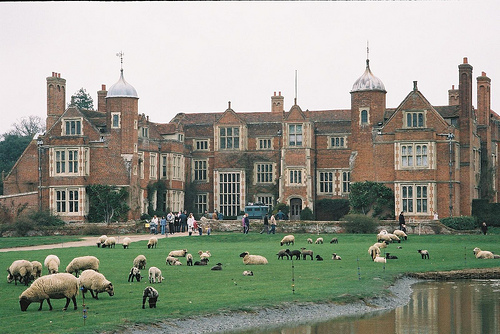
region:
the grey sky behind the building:
[13, 20, 485, 37]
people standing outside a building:
[146, 211, 284, 231]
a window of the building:
[401, 186, 426, 210]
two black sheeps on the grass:
[277, 248, 303, 261]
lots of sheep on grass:
[8, 235, 496, 302]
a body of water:
[231, 268, 491, 331]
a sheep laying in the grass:
[238, 250, 268, 265]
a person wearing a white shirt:
[183, 213, 195, 233]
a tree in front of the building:
[81, 178, 129, 229]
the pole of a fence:
[288, 261, 300, 295]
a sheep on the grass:
[18, 272, 79, 309]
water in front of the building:
[333, 270, 498, 327]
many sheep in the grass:
[7, 218, 496, 314]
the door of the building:
[289, 196, 304, 218]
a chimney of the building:
[46, 73, 62, 120]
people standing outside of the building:
[142, 208, 283, 235]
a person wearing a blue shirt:
[158, 216, 167, 231]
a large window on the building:
[218, 173, 238, 217]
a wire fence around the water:
[38, 241, 496, 321]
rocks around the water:
[191, 302, 405, 332]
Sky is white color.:
[148, 20, 294, 87]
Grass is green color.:
[41, 251, 322, 295]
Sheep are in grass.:
[6, 228, 412, 316]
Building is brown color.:
[36, 110, 448, 212]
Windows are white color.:
[51, 116, 442, 221]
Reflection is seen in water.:
[368, 273, 494, 333]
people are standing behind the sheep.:
[141, 201, 290, 236]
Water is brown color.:
[307, 271, 499, 329]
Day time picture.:
[16, 30, 491, 317]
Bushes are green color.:
[316, 179, 389, 226]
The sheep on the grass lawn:
[6, 228, 496, 310]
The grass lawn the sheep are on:
[2, 229, 499, 331]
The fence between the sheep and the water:
[4, 243, 497, 331]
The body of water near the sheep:
[225, 273, 497, 332]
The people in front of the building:
[144, 207, 495, 239]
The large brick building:
[0, 38, 499, 238]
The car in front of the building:
[238, 200, 289, 222]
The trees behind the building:
[1, 84, 98, 175]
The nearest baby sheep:
[138, 283, 161, 308]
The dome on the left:
[101, 65, 143, 97]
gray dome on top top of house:
[347, 61, 384, 92]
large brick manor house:
[2, 55, 499, 234]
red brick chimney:
[46, 77, 68, 125]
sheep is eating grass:
[19, 270, 79, 310]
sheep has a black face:
[18, 295, 30, 309]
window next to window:
[401, 185, 412, 213]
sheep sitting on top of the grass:
[238, 250, 265, 263]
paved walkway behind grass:
[0, 227, 192, 252]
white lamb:
[148, 267, 165, 282]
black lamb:
[211, 260, 223, 271]